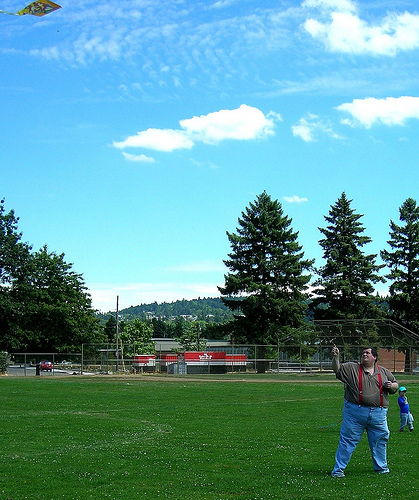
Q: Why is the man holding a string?
A: He is flying a kite.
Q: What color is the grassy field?
A: Green.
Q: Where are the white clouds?
A: In the blue sky.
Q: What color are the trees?
A: Green.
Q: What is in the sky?
A: White clouds.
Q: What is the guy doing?
A: Flying a kite.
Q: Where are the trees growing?
A: In the park.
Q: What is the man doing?
A: The man is flying a kite.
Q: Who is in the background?
A: A little boy.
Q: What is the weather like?
A: Partly cloudy and cool.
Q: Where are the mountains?
A: Behind the trees.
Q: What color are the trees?
A: Dark green.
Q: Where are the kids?
A: There is 1 kid there.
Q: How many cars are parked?
A: 1.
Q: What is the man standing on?
A: The grass.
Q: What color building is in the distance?
A: Red.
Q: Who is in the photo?
A: A man and boy.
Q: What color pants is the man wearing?
A: Blue.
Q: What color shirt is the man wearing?
A: Brown.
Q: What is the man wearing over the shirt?
A: Suspenders.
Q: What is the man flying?
A: A kite.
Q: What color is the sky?
A: Blue.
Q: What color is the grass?
A: It is green.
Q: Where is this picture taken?
A: In a field.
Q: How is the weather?
A: It is clear.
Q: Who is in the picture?
A: A man and a boy.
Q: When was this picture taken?
A: Daytime.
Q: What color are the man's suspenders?
A: Red.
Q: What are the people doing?
A: Flying kites.